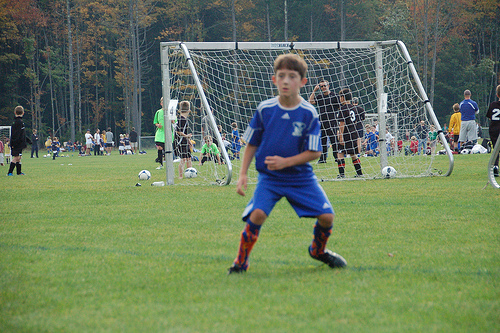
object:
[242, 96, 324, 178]
teeshirt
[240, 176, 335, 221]
shorts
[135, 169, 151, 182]
balls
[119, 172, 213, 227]
ground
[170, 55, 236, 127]
net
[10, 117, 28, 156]
uniform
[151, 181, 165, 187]
bottle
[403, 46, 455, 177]
pole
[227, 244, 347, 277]
shoes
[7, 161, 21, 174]
socks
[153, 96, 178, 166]
kids